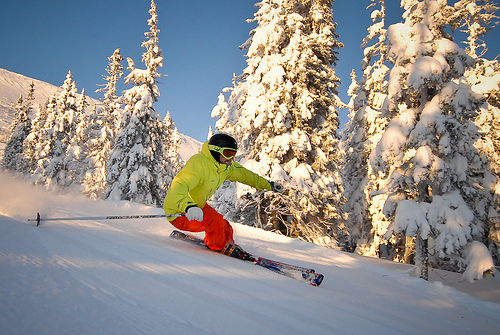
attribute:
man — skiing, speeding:
[153, 142, 285, 263]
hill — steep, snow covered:
[1, 69, 499, 334]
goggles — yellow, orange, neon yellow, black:
[212, 143, 241, 162]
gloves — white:
[181, 175, 291, 225]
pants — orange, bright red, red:
[166, 203, 248, 257]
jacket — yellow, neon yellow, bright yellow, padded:
[162, 147, 277, 216]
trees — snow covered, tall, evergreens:
[2, 0, 500, 275]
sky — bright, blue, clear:
[1, 1, 499, 157]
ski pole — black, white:
[25, 202, 189, 230]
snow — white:
[2, 68, 499, 335]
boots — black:
[214, 232, 254, 264]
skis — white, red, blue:
[166, 227, 333, 286]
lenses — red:
[222, 149, 247, 159]